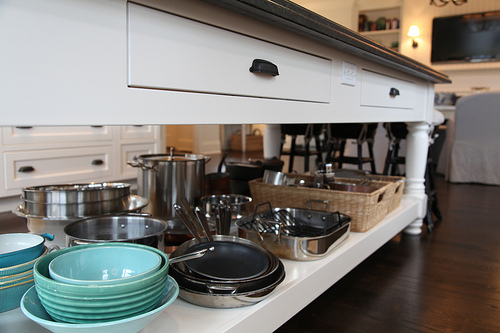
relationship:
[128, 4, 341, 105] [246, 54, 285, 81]
drawer with handle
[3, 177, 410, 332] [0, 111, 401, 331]
white shelf with many different kitchen items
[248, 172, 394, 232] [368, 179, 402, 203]
basket with hand holes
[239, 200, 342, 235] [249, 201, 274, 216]
rack with handle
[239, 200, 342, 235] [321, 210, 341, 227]
rack with handle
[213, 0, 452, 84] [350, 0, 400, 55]
edge of a shelf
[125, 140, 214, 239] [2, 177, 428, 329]
cookware on shelf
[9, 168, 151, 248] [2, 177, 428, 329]
cookware on shelf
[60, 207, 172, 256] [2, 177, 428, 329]
cookware on shelf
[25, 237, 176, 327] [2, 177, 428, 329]
cookware on shelf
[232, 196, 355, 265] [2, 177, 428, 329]
cookware on shelf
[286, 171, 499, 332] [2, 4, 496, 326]
floor in room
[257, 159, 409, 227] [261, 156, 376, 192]
basket filled with items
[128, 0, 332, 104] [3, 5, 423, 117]
drawer on shelf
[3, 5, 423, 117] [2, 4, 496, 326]
shelf in room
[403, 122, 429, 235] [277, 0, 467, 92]
leg to shelf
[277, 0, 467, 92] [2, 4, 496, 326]
shelf in room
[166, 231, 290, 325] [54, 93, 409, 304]
pans on a shelf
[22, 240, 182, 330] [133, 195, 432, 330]
bowls on a shelf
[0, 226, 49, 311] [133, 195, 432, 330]
bowls on a shelf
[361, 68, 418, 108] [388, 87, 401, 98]
drawer with handle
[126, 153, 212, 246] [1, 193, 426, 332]
cookware on shelf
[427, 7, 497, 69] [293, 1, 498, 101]
tv on wall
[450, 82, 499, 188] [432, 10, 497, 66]
chair in front of tv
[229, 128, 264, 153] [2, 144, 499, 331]
basket on floor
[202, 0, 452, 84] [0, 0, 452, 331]
edge of counter top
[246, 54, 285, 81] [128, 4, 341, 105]
handle of drawer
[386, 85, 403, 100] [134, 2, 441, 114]
handle of drawer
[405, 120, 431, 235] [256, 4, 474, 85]
leg of counter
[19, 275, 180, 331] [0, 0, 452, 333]
bowl on counter top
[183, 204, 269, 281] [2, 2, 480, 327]
pans on counter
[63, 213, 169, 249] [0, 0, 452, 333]
cookware on counter top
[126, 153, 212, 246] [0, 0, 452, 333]
cookware on counter top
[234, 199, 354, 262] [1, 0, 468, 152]
cookware on counter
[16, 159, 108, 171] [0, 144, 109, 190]
black handles on drawer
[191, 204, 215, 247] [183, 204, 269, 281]
handle on pans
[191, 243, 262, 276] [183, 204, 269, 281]
coating in pans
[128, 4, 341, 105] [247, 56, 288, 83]
drawer has handle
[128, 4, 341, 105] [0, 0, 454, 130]
drawer on shelf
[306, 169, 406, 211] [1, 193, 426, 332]
basket sitting on shelf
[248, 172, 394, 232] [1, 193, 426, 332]
basket sitting on shelf